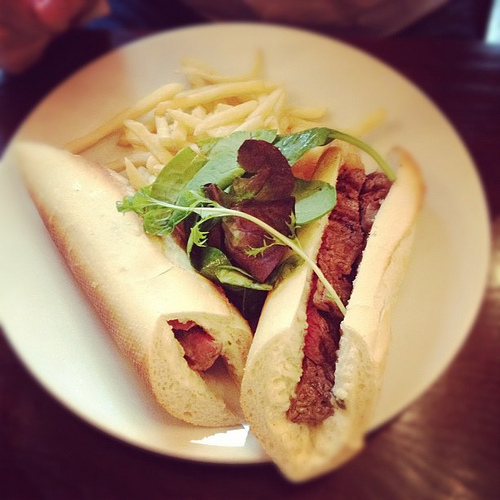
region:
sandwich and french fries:
[32, 25, 466, 468]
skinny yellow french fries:
[80, 65, 290, 180]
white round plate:
[17, 86, 446, 466]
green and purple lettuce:
[150, 127, 316, 288]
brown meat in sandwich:
[275, 147, 386, 428]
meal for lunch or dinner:
[26, 85, 452, 467]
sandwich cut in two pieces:
[50, 135, 426, 441]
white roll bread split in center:
[255, 227, 353, 477]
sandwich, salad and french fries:
[75, 85, 396, 445]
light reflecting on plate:
[189, 415, 260, 464]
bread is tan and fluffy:
[247, 141, 422, 476]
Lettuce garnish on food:
[170, 142, 308, 264]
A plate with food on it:
[44, 59, 348, 480]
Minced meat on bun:
[265, 240, 362, 432]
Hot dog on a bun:
[95, 245, 252, 437]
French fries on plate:
[122, 64, 282, 152]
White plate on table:
[9, 262, 94, 402]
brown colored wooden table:
[396, 432, 457, 497]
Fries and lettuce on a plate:
[95, 78, 290, 273]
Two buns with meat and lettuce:
[43, 160, 419, 474]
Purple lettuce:
[224, 173, 289, 277]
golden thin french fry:
[164, 78, 284, 109]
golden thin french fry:
[123, 114, 180, 166]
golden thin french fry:
[120, 155, 156, 190]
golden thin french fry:
[333, 100, 393, 146]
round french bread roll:
[15, 135, 254, 428]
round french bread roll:
[225, 146, 406, 478]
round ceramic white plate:
[1, 18, 498, 461]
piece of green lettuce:
[123, 191, 350, 316]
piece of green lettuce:
[290, 168, 343, 230]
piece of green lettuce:
[156, 133, 271, 202]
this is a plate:
[16, 245, 56, 329]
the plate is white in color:
[17, 273, 64, 333]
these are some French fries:
[134, 76, 291, 126]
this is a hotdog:
[287, 150, 382, 455]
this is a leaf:
[186, 132, 313, 171]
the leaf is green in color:
[212, 145, 227, 170]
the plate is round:
[0, 27, 493, 464]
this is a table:
[5, 412, 42, 477]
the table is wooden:
[7, 413, 57, 484]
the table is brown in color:
[434, 52, 469, 80]